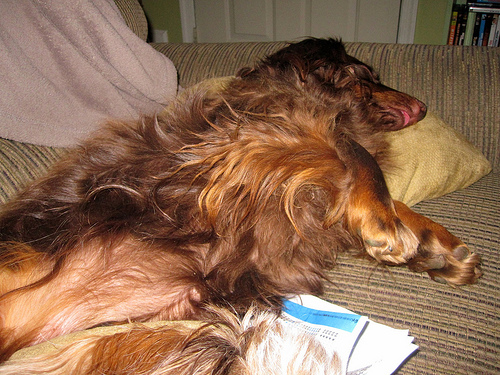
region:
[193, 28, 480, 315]
very hairy dog sleeping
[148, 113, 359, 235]
dog has orange red hair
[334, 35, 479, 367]
couch is brown with woven fabric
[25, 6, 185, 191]
blanket draped over couch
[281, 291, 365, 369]
dog is on the newspaper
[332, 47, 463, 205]
dogs head is on the pillow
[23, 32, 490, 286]
dog is sleeping on his back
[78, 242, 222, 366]
dog has a pink belly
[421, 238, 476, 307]
brown paw pads of the dog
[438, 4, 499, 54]
books on a bookshelf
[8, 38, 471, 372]
Dog laying on a couch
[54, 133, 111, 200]
Patch of long hair on a dog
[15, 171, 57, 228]
Patch of long hair on a dog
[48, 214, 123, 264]
Patch of long hair on a dog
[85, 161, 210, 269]
Patch of long hair on a dog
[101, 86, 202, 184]
Patch of long hair on a dog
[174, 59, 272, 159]
Patch of long hair on a dog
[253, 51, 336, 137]
Patch of long hair on a dog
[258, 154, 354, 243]
Patch of long hair on a dog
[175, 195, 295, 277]
Patch of long hair on a dog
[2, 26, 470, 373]
a dog on a couch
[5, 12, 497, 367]
a dog on a sofa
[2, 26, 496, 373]
a dog sleeping on a couch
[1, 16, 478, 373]
a dog sleeping on a sofa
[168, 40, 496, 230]
a dog laying on a pillow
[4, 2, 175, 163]
a blanket on a couch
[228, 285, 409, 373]
paper on a couch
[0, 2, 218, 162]
a blanket on the back of a couch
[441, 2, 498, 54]
books on a shelf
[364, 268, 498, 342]
stripes on a couch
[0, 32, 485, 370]
a dog sleeping on the sofa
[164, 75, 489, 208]
a pillow under the dog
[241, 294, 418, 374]
papers laying by the dog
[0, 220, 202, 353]
a person's hand petting the dog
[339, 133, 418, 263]
right front paw of the pooch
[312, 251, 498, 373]
striped fabric on the sofa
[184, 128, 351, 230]
a patch of gold hair on the dog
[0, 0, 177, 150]
a pink towel on the sofa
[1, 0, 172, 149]
a rumpled piece of pink cloth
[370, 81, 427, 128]
the snout of a sleeping dog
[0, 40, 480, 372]
A furry brown dog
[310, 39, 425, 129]
Head of the sleeping dog resting on a cushion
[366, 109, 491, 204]
The golden colored cushion the dog's head is resting on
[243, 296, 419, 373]
A sheaf of papers on the sofa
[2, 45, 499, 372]
The brown sofa the dog is sleeping on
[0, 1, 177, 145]
A beige towel thrown on the sofa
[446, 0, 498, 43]
Some books in a bookcase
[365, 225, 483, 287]
Front paws of the dog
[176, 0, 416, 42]
Part of a closed door visible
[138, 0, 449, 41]
A small part of green wall